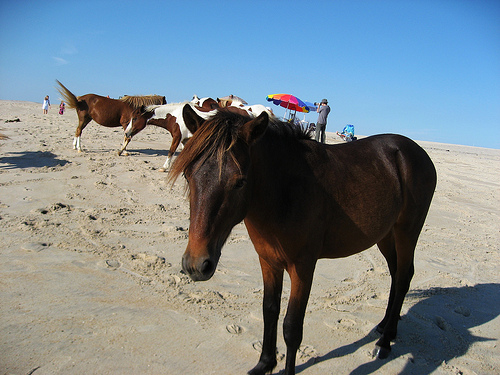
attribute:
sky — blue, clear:
[1, 4, 499, 150]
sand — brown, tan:
[1, 102, 499, 371]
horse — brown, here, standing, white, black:
[168, 101, 438, 373]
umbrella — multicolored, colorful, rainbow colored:
[262, 92, 309, 121]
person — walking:
[41, 95, 51, 114]